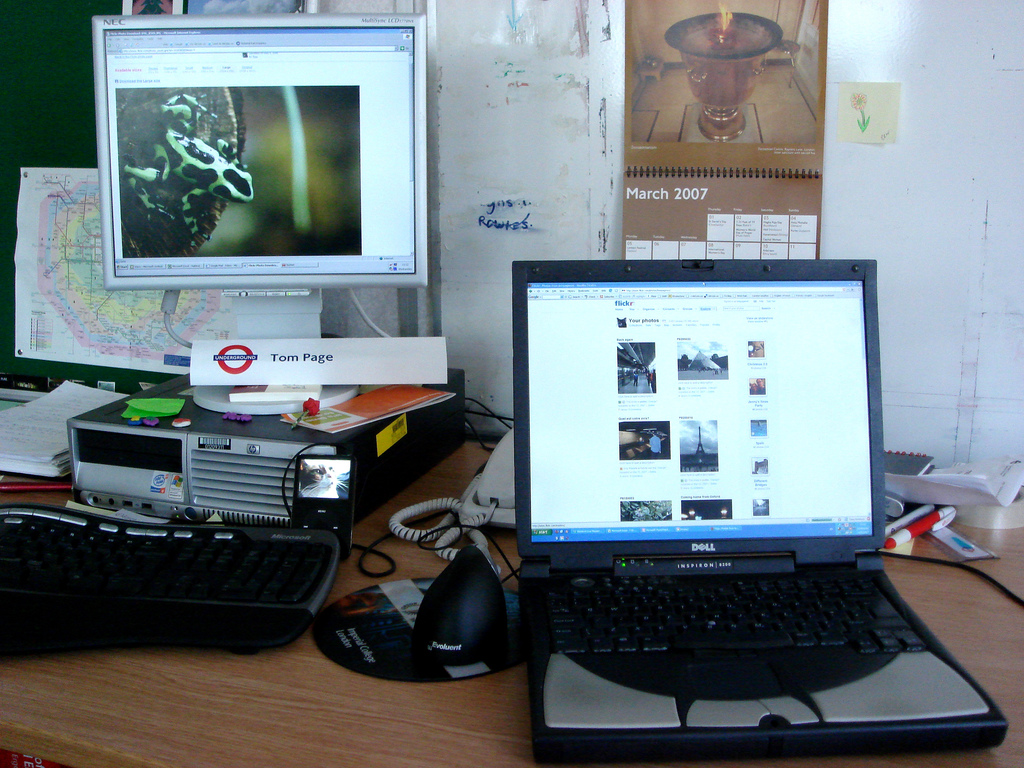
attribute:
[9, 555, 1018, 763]
desk — brown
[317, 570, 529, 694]
mouse pad — round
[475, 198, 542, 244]
note — black, small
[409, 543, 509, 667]
computer mouse — black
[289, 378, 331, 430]
flower — red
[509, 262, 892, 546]
monitor — desktop computer 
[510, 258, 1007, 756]
laptop — black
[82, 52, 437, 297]
monitor — computer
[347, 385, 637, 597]
phone — white, corded, landline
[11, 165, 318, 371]
map — Colorful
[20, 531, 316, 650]
keyboard — black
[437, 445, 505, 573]
phone — white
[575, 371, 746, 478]
laptop — black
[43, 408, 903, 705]
desk — covered